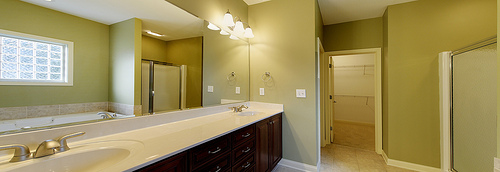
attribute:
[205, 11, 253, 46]
lights — hanging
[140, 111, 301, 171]
cabinets — wooden, dark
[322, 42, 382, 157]
door — here, open, big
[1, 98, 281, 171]
counter — long, white, wooden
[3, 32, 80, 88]
window — frosted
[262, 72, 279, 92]
rack — empty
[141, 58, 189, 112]
shower door — reflected, glass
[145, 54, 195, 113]
mirror — large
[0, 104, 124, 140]
bathtub — reflected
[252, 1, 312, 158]
wall — light green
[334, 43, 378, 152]
closet — big, large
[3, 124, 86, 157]
handles — silver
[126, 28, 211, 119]
wall — beige